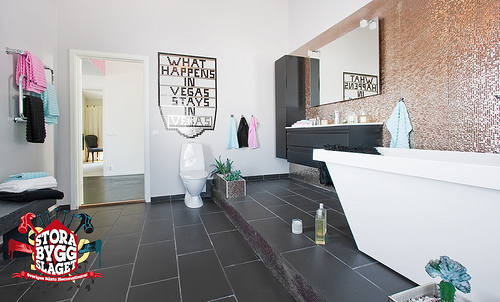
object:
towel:
[386, 101, 412, 149]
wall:
[296, 32, 500, 144]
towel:
[15, 51, 46, 95]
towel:
[23, 95, 47, 144]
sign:
[158, 52, 219, 138]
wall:
[60, 7, 278, 182]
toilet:
[178, 143, 208, 208]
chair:
[85, 134, 103, 163]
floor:
[26, 192, 368, 300]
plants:
[207, 155, 234, 178]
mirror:
[309, 16, 380, 108]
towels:
[237, 117, 250, 149]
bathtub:
[311, 146, 500, 302]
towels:
[0, 176, 58, 194]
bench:
[1, 197, 59, 260]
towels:
[32, 84, 60, 124]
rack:
[5, 44, 55, 125]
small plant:
[224, 169, 242, 181]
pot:
[213, 172, 248, 198]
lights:
[360, 20, 368, 28]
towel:
[226, 117, 239, 149]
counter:
[285, 122, 384, 129]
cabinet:
[286, 123, 382, 170]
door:
[67, 49, 148, 210]